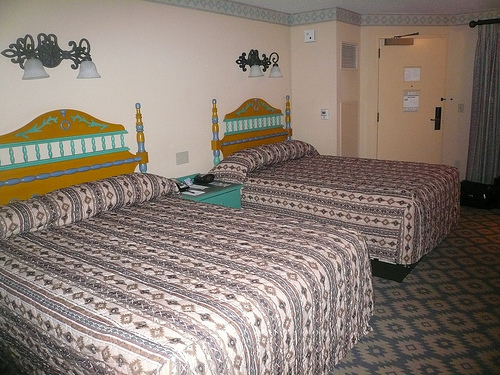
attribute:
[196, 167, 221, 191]
clock — alarm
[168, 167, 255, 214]
night table — green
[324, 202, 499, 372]
carpet — blue, tan, white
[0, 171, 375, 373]
bed spread — white, black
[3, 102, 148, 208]
headboard — colorful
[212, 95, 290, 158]
headboard — colorful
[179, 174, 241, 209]
desk — green